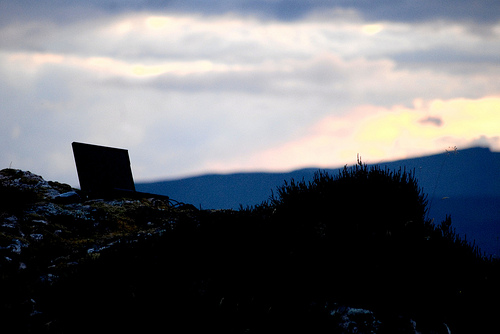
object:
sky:
[0, 0, 499, 147]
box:
[64, 141, 163, 198]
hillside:
[13, 175, 183, 333]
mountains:
[175, 148, 498, 225]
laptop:
[68, 139, 152, 192]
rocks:
[56, 190, 78, 205]